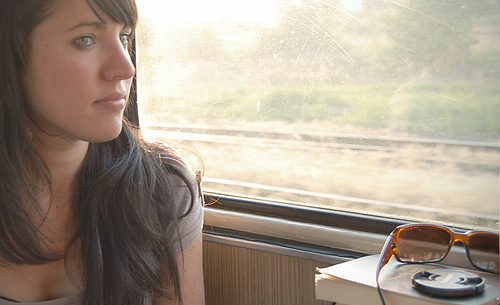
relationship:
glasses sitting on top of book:
[371, 220, 483, 303] [310, 248, 484, 303]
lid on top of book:
[410, 266, 484, 299] [310, 248, 484, 303]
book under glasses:
[310, 248, 484, 303] [371, 220, 483, 303]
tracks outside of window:
[139, 116, 484, 232] [134, 0, 484, 236]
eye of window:
[69, 30, 97, 49] [2, 0, 208, 302]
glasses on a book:
[371, 220, 500, 303] [310, 248, 484, 303]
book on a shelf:
[310, 248, 484, 303] [308, 294, 344, 303]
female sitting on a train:
[1, 1, 205, 304] [124, 0, 484, 302]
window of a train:
[134, 0, 484, 236] [124, 0, 484, 302]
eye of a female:
[69, 30, 97, 49] [1, 1, 205, 304]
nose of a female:
[100, 37, 138, 85] [1, 1, 205, 304]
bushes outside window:
[202, 79, 484, 136] [134, 0, 484, 236]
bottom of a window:
[199, 186, 398, 259] [134, 0, 484, 236]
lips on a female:
[94, 90, 129, 109] [1, 1, 205, 304]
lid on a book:
[410, 266, 484, 299] [310, 248, 484, 303]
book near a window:
[310, 248, 484, 303] [134, 0, 484, 236]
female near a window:
[1, 1, 209, 301] [134, 0, 484, 236]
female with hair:
[1, 1, 205, 304] [0, 0, 216, 302]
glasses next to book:
[371, 220, 500, 303] [313, 254, 494, 299]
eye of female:
[69, 30, 97, 49] [1, 1, 205, 304]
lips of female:
[94, 90, 129, 109] [1, 1, 205, 304]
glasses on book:
[371, 220, 500, 303] [313, 250, 497, 302]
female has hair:
[1, 1, 205, 304] [0, 0, 216, 302]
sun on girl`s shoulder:
[139, 77, 200, 171] [135, 135, 201, 188]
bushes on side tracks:
[190, 83, 495, 135] [140, 121, 497, 228]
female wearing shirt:
[1, 1, 205, 304] [5, 153, 205, 301]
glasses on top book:
[371, 220, 500, 303] [310, 254, 498, 304]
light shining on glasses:
[396, 250, 443, 264] [371, 220, 500, 303]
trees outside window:
[141, 3, 496, 85] [135, 3, 497, 218]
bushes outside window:
[139, 84, 497, 144] [135, 3, 497, 218]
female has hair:
[1, 1, 205, 304] [3, 0, 195, 302]